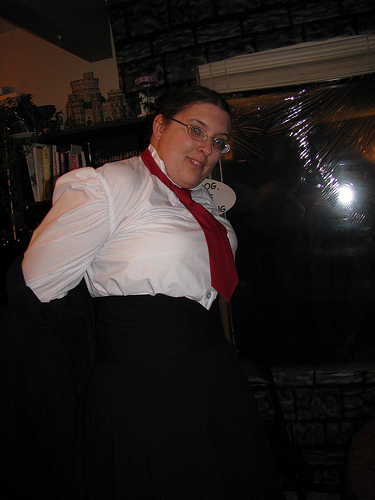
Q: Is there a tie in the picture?
A: Yes, there is a tie.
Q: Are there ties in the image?
A: Yes, there is a tie.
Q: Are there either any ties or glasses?
A: Yes, there is a tie.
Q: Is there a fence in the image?
A: No, there are no fences.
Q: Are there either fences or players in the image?
A: No, there are no fences or players.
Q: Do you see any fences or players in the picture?
A: No, there are no fences or players.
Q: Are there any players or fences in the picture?
A: No, there are no fences or players.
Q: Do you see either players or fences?
A: No, there are no fences or players.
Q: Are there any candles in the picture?
A: No, there are no candles.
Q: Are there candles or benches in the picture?
A: No, there are no candles or benches.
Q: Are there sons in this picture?
A: No, there are no sons.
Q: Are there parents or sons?
A: No, there are no sons or parents.